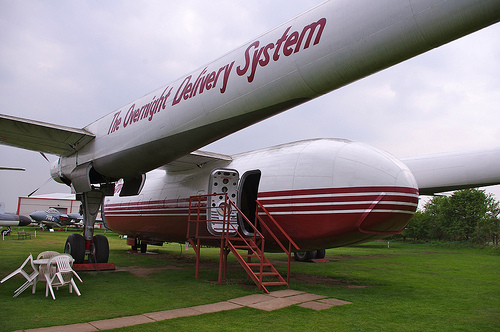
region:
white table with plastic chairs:
[3, 243, 90, 303]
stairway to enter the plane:
[181, 189, 302, 301]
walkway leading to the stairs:
[19, 279, 366, 329]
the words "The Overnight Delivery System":
[87, 9, 365, 151]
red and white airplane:
[1, 5, 493, 298]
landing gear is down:
[59, 182, 115, 264]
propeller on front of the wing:
[21, 139, 83, 208]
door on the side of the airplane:
[199, 162, 264, 234]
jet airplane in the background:
[24, 200, 76, 230]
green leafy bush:
[415, 180, 498, 256]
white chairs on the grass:
[10, 238, 83, 303]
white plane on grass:
[0, 25, 496, 300]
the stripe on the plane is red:
[89, 177, 430, 238]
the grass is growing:
[1, 220, 487, 320]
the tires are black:
[56, 225, 116, 268]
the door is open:
[202, 153, 274, 249]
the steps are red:
[191, 190, 302, 298]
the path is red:
[7, 282, 343, 328]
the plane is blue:
[25, 197, 85, 234]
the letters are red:
[101, 16, 353, 156]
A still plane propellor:
[27, 145, 92, 199]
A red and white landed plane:
[1, 0, 498, 264]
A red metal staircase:
[188, 190, 303, 295]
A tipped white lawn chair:
[1, 249, 39, 300]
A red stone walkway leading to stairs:
[4, 284, 355, 330]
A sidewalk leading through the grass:
[4, 282, 357, 329]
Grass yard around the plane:
[0, 225, 499, 329]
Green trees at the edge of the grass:
[418, 185, 498, 246]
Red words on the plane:
[86, 13, 331, 136]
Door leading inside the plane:
[202, 163, 269, 238]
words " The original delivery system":
[108, 18, 325, 132]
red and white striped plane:
[101, 138, 421, 243]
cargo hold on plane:
[100, 141, 411, 245]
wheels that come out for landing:
[122, 232, 333, 264]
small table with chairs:
[3, 251, 78, 299]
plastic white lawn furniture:
[2, 249, 82, 297]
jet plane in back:
[12, 204, 80, 231]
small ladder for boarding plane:
[184, 189, 296, 290]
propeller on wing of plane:
[19, 139, 117, 210]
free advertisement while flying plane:
[97, 15, 333, 133]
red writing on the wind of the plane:
[84, 16, 326, 125]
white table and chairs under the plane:
[7, 245, 85, 301]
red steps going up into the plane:
[191, 185, 291, 299]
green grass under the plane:
[379, 263, 451, 323]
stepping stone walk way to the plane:
[100, 288, 345, 323]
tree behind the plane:
[434, 189, 496, 248]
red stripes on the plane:
[269, 183, 371, 216]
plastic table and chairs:
[1, 236, 86, 302]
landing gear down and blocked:
[63, 233, 120, 273]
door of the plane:
[210, 162, 244, 239]